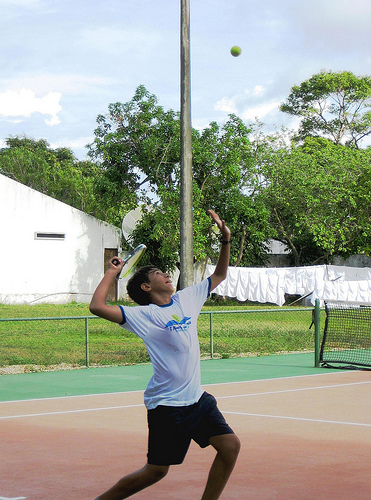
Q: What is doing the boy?
A: Hitting a ball.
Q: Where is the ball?
A: In the air.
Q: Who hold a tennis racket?
A: A boy.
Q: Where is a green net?
A: In a tennis court.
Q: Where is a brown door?
A: In a house.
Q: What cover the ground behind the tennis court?
A: Grass.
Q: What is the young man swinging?
A: A tennis racket.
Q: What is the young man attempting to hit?
A: A tennis ball.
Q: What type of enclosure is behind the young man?
A: A chain link fence.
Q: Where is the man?
A: On a tennis court.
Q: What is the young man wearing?
A: Shorts and a t-shirt.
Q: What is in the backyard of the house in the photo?
A: A clothesline with sheets hanging.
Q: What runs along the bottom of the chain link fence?
A: A trail of dirt.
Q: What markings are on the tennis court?
A: Boundary lines.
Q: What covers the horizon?
A: Large leaf filled trees.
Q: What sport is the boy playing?
A: Tennis.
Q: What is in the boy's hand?
A: A tennis racket.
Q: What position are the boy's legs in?
A: They are bent.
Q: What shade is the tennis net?
A: Black and white.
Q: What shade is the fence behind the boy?
A: Silver.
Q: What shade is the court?
A: Red.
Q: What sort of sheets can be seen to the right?
A: White sheets.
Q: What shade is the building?
A: White.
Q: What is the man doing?
A: Playing tennis.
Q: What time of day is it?
A: Daytime.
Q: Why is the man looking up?
A: He is preparing to hit the ball.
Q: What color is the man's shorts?
A: Black.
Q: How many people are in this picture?
A: One.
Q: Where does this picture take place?
A: On a tennis court.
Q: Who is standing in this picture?
A: A man.